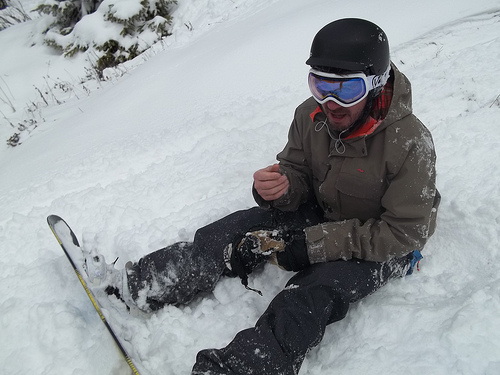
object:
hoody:
[250, 59, 441, 271]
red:
[367, 119, 374, 124]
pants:
[124, 203, 418, 375]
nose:
[327, 101, 341, 110]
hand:
[250, 225, 310, 271]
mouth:
[328, 110, 348, 122]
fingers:
[253, 163, 290, 201]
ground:
[0, 0, 499, 375]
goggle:
[308, 72, 366, 102]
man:
[125, 16, 437, 375]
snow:
[196, 307, 246, 334]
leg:
[188, 259, 382, 375]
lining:
[309, 68, 366, 79]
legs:
[124, 203, 292, 313]